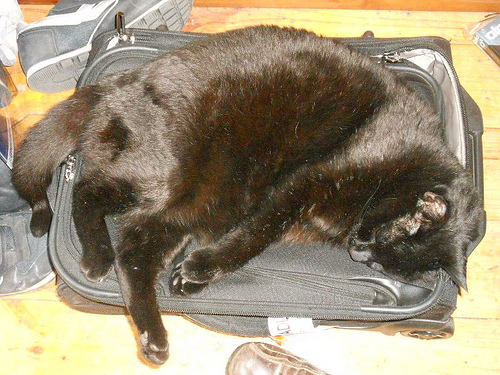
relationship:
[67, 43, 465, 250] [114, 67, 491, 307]
black cat lying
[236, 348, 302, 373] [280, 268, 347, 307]
brown shoe by suitcase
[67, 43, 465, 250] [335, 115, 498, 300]
black ears on cat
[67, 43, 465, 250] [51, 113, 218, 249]
black tail on cat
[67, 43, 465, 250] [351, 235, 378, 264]
black cats nose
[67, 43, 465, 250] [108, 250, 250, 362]
black cats long feet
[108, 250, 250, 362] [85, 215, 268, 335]
two black front paws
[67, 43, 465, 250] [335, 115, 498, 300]
black head of cat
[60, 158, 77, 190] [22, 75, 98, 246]
zipper between cats tail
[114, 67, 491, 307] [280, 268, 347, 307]
small black suitcase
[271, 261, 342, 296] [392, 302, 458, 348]
black wheel on suitcase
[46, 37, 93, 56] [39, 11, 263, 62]
black tennis shoe above suitcase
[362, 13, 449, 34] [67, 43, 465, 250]
wood floor under cat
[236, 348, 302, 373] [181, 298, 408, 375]
brown shoe front of suitcase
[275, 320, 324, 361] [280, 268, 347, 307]
white tag on suitcase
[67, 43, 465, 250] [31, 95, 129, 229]
black tail of cat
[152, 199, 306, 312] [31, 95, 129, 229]
front paws of cat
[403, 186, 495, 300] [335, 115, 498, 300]
ears on cat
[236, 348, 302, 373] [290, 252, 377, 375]
brown shoe next to bag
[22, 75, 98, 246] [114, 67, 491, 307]
tail of cat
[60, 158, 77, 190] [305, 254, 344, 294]
zipper on bag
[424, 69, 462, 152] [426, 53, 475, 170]
grey shoe in bag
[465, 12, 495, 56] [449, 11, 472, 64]
book on floor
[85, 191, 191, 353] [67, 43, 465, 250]
leg of cat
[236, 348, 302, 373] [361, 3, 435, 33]
brown tiles in flooring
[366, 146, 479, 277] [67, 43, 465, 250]
head of cat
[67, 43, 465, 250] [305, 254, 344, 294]
cat sleeping on bag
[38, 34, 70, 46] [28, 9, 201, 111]
gray ten shoe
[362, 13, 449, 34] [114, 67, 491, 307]
wood table under cat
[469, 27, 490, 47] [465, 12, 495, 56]
corner of book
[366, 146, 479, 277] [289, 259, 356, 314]
cat head laying on suitcase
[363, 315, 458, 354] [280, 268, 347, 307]
wheel on suitcase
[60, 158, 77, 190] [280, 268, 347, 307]
zipper on suitcase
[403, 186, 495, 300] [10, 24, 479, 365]
ears of cat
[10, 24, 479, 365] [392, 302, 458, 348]
cat sleeping on suitcase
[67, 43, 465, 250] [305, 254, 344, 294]
black cat sleeping on bag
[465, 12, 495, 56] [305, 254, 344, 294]
book near bag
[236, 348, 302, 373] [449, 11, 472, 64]
brown colored floor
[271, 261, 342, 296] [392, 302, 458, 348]
black wheel on bag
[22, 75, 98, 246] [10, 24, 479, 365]
tail of cat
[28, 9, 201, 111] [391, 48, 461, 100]
shoe near bag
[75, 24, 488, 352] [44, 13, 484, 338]
cat on bag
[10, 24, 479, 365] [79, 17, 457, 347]
cat on suitcase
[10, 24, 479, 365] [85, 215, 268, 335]
cat has paws